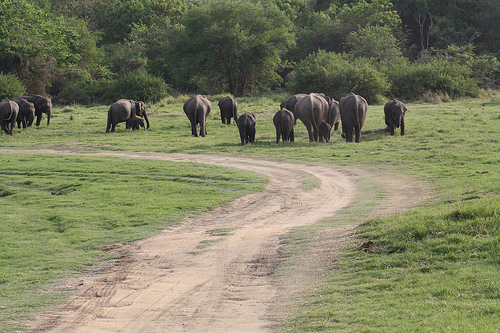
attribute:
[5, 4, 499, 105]
trees — short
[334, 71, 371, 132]
elephant — gray, big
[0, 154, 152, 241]
grass — short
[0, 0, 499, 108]
leaves — green 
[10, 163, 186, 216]
grass — green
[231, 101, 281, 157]
elephant — grey 